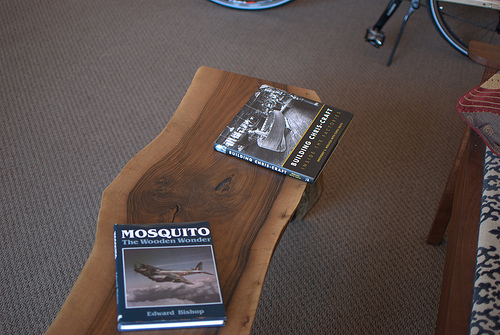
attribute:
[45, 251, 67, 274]
carpet — brown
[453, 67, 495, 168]
pillow — decor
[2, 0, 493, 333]
carpet — brown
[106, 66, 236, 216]
table — wooden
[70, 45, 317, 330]
coffee table — wooden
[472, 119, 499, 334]
cushion — blue, black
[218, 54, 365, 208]
books — brown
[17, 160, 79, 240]
carpet — brown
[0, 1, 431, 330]
carpet — brown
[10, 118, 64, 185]
carpet — brown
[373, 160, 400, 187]
carpet — brown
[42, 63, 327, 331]
table — brown, coffee table, wooden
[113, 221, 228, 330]
book — BLUE